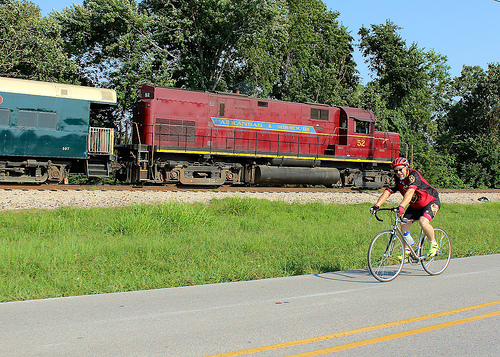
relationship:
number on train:
[355, 136, 368, 150] [40, 60, 390, 209]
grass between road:
[1, 197, 498, 302] [1, 248, 498, 353]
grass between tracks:
[1, 197, 498, 302] [2, 184, 498, 193]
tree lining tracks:
[0, 0, 500, 191] [0, 174, 499, 194]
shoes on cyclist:
[392, 242, 446, 261] [368, 157, 440, 263]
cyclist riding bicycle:
[368, 157, 440, 263] [354, 197, 461, 282]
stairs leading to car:
[85, 156, 110, 181] [0, 77, 118, 159]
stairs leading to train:
[85, 156, 110, 181] [0, 63, 121, 194]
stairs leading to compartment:
[85, 156, 110, 181] [0, 88, 90, 165]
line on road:
[286, 293, 498, 354] [0, 254, 500, 357]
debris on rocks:
[470, 191, 493, 213] [0, 189, 500, 212]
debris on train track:
[470, 191, 493, 213] [2, 164, 499, 201]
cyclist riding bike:
[368, 157, 440, 263] [367, 197, 454, 288]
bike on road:
[367, 206, 451, 282] [0, 254, 500, 357]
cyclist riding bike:
[368, 157, 440, 263] [367, 206, 451, 282]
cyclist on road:
[368, 157, 440, 263] [0, 254, 500, 357]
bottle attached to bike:
[401, 230, 416, 247] [367, 206, 451, 282]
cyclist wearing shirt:
[368, 157, 440, 263] [408, 174, 435, 210]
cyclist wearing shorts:
[368, 157, 440, 263] [381, 189, 445, 229]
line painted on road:
[209, 301, 498, 357] [1, 248, 498, 353]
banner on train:
[208, 115, 317, 135] [0, 77, 414, 192]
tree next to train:
[0, 0, 500, 191] [0, 77, 414, 192]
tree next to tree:
[104, 35, 179, 166] [0, 0, 500, 191]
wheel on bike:
[366, 225, 408, 286] [352, 203, 455, 290]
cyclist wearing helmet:
[368, 157, 440, 263] [388, 158, 410, 170]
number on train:
[355, 136, 368, 150] [1, 72, 401, 185]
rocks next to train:
[1, 175, 498, 208] [0, 62, 420, 191]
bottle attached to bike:
[403, 231, 415, 246] [364, 202, 456, 284]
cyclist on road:
[335, 154, 479, 275] [19, 261, 486, 352]